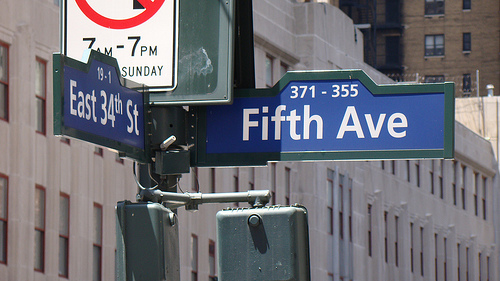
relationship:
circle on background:
[78, 1, 163, 29] [63, 1, 177, 88]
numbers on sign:
[91, 62, 116, 84] [47, 46, 156, 166]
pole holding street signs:
[115, 90, 217, 211] [27, 38, 457, 173]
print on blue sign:
[238, 104, 325, 143] [191, 67, 457, 166]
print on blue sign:
[327, 101, 416, 139] [191, 67, 457, 166]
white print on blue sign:
[288, 80, 318, 107] [191, 67, 457, 166]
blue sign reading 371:
[191, 67, 457, 166] [285, 77, 319, 98]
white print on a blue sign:
[330, 76, 361, 98] [191, 67, 457, 166]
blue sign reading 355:
[191, 67, 457, 166] [329, 82, 359, 98]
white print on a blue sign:
[238, 105, 407, 142] [191, 71, 456, 165]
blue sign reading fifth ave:
[191, 71, 456, 165] [243, 105, 408, 142]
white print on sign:
[97, 80, 122, 136] [53, 49, 150, 163]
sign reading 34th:
[53, 49, 150, 163] [97, 91, 123, 129]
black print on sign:
[128, 32, 166, 62] [455, 70, 497, 130]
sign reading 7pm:
[455, 70, 497, 130] [128, 31, 160, 57]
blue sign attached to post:
[191, 67, 457, 166] [102, 36, 205, 268]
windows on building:
[405, 215, 427, 275] [2, 1, 496, 267]